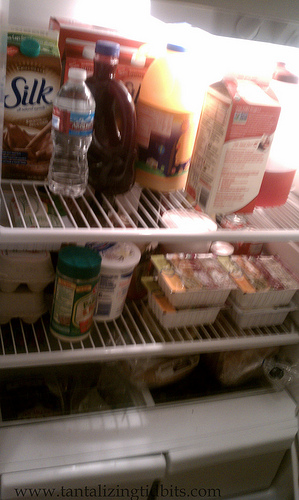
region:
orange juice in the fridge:
[139, 37, 190, 187]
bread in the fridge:
[213, 345, 298, 388]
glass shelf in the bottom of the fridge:
[6, 375, 278, 433]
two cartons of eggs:
[4, 247, 47, 326]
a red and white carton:
[207, 70, 264, 224]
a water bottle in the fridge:
[52, 69, 88, 195]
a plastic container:
[91, 242, 129, 313]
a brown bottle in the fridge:
[82, 41, 137, 196]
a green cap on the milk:
[18, 35, 40, 52]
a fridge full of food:
[2, 3, 287, 495]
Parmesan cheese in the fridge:
[53, 247, 98, 340]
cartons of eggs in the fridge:
[2, 253, 46, 315]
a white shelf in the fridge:
[4, 178, 297, 238]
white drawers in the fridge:
[7, 442, 285, 494]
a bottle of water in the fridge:
[56, 66, 90, 192]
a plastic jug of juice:
[135, 42, 193, 191]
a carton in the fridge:
[194, 67, 274, 217]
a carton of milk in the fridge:
[6, 30, 54, 185]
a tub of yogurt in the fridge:
[86, 238, 135, 323]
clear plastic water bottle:
[46, 62, 93, 199]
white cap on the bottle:
[68, 68, 86, 79]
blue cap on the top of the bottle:
[163, 39, 182, 54]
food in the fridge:
[5, 1, 298, 498]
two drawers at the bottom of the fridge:
[2, 421, 298, 498]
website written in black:
[7, 480, 235, 498]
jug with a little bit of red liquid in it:
[253, 63, 296, 211]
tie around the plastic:
[258, 355, 268, 370]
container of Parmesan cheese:
[48, 245, 103, 342]